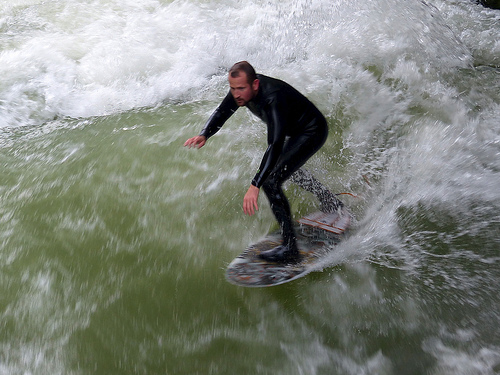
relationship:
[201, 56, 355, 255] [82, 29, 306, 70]
man surfing wave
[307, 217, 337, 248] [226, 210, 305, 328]
patterned a surfboard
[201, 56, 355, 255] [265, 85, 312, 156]
man in a shiny wetsuit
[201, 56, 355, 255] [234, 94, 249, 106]
man with a goatee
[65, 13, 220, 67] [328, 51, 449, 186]
white form from wave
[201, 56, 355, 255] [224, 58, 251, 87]
man with short hair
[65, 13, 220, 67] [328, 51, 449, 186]
crashing a wave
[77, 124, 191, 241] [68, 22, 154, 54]
green clear water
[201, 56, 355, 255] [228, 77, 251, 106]
man with a concentrating face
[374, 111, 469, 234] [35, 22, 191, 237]
splashing water in ocean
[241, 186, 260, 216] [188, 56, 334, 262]
hand of man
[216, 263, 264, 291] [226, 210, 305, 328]
tip of surfboard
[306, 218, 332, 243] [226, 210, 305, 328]
logo on surfboard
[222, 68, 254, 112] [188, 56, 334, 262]
facial expression of man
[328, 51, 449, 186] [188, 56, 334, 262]
waves ridden by man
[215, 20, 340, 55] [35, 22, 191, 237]
waves of ocean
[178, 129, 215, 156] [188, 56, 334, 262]
right hand of man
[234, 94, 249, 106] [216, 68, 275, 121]
beard on surfers face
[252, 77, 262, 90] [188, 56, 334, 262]
left ear of man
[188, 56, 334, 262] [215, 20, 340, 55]
man riding waves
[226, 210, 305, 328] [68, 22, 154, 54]
surfboard on water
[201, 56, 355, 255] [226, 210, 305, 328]
man on surfboard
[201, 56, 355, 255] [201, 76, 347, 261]
man wearing shiny wetsuit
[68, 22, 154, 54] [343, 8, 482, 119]
water not calm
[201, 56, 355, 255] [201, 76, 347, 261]
man in a shiny wetsuit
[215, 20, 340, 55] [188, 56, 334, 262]
waves behind man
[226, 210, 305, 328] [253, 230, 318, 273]
surfboard with a cool design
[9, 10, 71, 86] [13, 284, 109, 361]
appears to be lake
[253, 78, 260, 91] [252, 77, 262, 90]
left ear wet ear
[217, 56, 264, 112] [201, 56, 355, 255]
head of a person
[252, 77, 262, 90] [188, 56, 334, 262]
left ear of a man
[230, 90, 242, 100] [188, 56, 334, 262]
nose of a man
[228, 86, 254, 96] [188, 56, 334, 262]
eye of a man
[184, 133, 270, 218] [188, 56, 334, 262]
hand of a man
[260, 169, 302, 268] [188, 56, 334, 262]
leg of a man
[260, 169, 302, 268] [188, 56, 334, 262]
leg of man